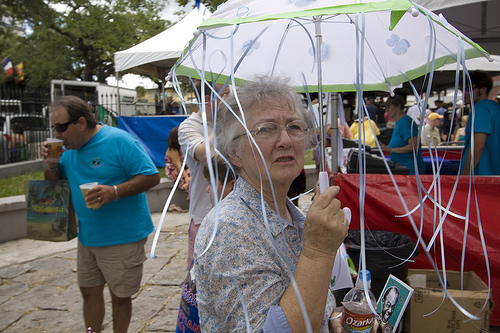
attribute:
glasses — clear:
[239, 129, 375, 158]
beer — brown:
[37, 147, 96, 175]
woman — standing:
[105, 133, 422, 299]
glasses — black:
[36, 125, 83, 130]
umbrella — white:
[218, 21, 438, 91]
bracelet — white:
[109, 169, 115, 202]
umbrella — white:
[199, 13, 380, 84]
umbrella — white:
[267, 33, 308, 64]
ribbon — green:
[374, 0, 414, 40]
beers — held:
[25, 128, 175, 248]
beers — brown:
[72, 117, 80, 227]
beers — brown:
[22, 123, 137, 264]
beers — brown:
[53, 141, 123, 248]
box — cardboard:
[395, 263, 495, 330]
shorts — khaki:
[71, 232, 148, 297]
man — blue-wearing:
[30, 97, 170, 329]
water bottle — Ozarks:
[336, 268, 380, 331]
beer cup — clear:
[45, 138, 65, 166]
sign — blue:
[376, 270, 418, 330]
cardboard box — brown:
[399, 262, 487, 331]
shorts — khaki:
[71, 237, 147, 301]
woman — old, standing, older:
[182, 70, 386, 329]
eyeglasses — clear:
[224, 115, 308, 149]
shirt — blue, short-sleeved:
[53, 127, 164, 251]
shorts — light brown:
[68, 234, 150, 303]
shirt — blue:
[184, 180, 307, 330]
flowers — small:
[226, 243, 254, 277]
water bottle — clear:
[338, 260, 379, 328]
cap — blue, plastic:
[356, 270, 372, 285]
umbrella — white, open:
[170, 3, 483, 96]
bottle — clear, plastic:
[336, 264, 381, 331]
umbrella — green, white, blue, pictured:
[171, 2, 492, 108]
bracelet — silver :
[108, 180, 127, 207]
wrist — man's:
[18, 77, 181, 330]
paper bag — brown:
[15, 163, 79, 272]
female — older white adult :
[172, 79, 386, 322]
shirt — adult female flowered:
[203, 189, 384, 304]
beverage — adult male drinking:
[25, 91, 178, 320]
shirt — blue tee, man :
[46, 131, 168, 247]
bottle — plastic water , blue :
[340, 269, 393, 331]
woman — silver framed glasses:
[154, 70, 418, 330]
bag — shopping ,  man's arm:
[6, 170, 86, 240]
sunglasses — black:
[43, 111, 85, 135]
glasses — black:
[43, 109, 83, 136]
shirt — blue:
[36, 122, 161, 245]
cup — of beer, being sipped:
[42, 136, 67, 166]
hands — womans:
[326, 287, 395, 330]